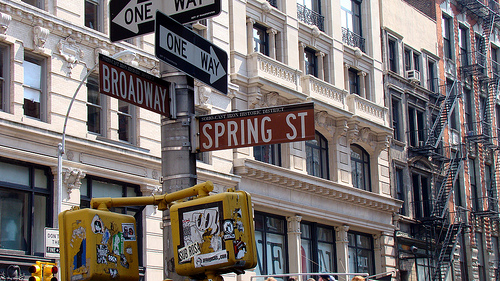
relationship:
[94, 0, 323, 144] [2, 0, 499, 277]
signs in front of a building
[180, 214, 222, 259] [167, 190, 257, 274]
sticker on light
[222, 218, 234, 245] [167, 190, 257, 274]
sticker on light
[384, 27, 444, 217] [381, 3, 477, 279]
stack of windows on a building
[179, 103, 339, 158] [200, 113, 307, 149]
sign with white lettering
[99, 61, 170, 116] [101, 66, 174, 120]
word broadway in white letters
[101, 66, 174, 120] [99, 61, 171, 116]
white letters on a red background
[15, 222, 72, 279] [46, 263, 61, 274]
stoplight with red light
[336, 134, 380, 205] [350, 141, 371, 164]
window with arch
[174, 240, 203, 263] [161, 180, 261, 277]
sticker on a sign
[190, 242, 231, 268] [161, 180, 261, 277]
sticker on a sign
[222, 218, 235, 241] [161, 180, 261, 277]
sticker on a sign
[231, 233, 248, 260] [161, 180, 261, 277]
sticker on a sign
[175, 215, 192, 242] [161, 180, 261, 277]
sticker on a sign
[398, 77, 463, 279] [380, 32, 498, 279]
fire-escape on a building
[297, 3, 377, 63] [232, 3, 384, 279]
planters balcony on a building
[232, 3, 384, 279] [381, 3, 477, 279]
building with building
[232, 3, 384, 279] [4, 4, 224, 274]
building with building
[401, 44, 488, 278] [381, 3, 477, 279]
fire escape on outside of a building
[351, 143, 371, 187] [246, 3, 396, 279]
window in a building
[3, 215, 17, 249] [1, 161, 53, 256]
person visible through a window